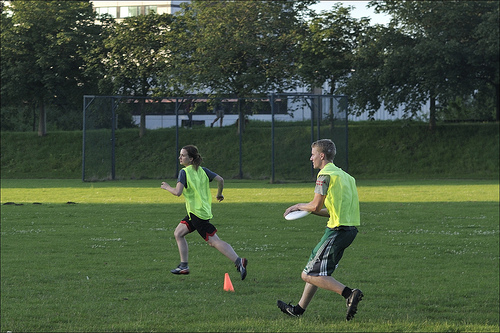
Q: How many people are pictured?
A: Two.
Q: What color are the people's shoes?
A: Black and white.